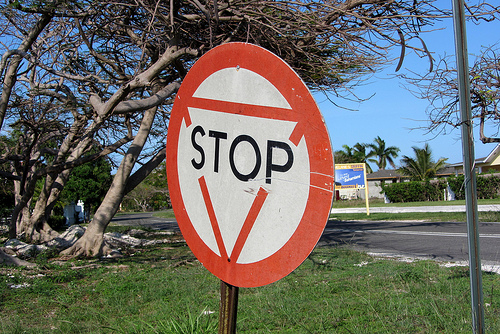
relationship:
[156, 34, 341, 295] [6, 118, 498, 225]
stop sign behind suburban area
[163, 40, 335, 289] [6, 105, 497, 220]
stop sign in suburban area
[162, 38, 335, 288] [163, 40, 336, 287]
border lining sign board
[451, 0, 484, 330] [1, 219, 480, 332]
pole standing in grass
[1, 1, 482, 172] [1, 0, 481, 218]
sky seen in distance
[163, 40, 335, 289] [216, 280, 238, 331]
stop sign mounted on pole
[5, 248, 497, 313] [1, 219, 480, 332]
snow on grass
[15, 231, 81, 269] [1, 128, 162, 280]
rocks by tree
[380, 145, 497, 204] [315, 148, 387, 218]
dwelling by sign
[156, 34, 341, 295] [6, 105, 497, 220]
stop sign in suburban area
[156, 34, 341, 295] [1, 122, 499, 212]
stop sign in suburban area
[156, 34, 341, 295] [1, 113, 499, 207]
stop sign in suburban area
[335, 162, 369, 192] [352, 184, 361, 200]
advertisement on pole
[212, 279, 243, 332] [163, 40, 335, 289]
pole for stop sign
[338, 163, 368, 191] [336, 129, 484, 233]
sign in background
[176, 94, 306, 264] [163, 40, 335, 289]
triangle on stop sign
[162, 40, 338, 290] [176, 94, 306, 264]
circle with triangle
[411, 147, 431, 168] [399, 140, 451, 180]
leaves on tree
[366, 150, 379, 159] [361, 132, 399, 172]
leaves on tree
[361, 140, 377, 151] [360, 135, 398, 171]
leaves on tree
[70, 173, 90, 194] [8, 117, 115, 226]
leaves on tree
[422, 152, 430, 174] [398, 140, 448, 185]
leaves on tree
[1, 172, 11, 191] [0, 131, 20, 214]
leaves on tree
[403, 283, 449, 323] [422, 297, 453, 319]
patch with growth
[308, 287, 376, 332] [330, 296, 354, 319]
grass with growth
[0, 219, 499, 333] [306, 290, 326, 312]
grass with growth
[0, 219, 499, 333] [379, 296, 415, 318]
grass with growth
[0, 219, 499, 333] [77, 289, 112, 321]
grass with growth